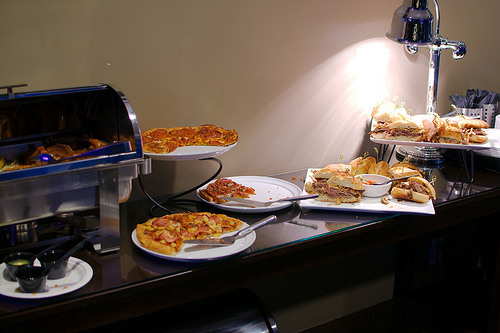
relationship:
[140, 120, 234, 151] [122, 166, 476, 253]
pizza on table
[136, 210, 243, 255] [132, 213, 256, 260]
pizza on plate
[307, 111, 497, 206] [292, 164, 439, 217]
sandwich on plate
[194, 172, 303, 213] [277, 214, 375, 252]
plate on table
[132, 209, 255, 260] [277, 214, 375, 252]
plate on table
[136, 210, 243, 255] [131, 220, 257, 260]
pizza on plate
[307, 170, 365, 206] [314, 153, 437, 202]
sandwich on platter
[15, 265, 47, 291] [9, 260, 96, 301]
bowl on plate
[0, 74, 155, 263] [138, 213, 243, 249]
tool for food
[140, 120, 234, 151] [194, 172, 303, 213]
pizza on plate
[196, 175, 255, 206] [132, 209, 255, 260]
pizza on plate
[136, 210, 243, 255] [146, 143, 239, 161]
pizza on plate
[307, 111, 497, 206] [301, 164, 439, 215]
sandwich on plate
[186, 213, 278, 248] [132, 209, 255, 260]
silver server on plate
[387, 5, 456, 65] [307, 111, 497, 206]
warming light by sandwich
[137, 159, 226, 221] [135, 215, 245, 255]
wires by food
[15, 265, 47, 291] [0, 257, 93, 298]
bowl on plate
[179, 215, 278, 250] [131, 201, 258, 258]
knife on plate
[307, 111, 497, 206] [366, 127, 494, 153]
sandwich on plate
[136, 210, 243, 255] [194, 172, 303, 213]
pizza on plate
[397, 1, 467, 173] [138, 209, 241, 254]
light above food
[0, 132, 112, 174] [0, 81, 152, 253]
food on tray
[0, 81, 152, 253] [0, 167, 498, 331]
tray on table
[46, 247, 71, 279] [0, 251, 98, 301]
bowl on plate